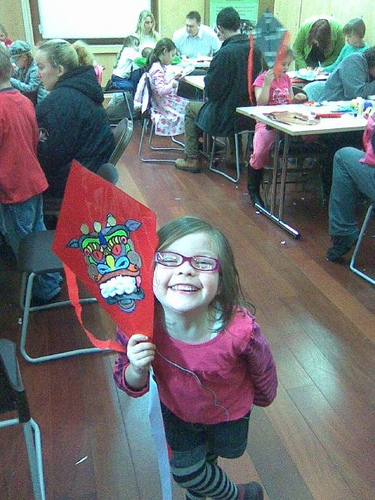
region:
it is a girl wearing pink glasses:
[156, 250, 220, 271]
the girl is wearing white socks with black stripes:
[180, 461, 217, 497]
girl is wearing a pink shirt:
[162, 338, 248, 423]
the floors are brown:
[285, 296, 351, 411]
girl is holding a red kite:
[64, 190, 166, 332]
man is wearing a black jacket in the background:
[204, 46, 258, 99]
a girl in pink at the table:
[259, 47, 294, 100]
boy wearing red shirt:
[1, 95, 48, 189]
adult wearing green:
[300, 15, 341, 65]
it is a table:
[245, 97, 371, 135]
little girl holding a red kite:
[51, 157, 160, 398]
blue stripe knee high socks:
[169, 462, 238, 498]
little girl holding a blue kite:
[246, 3, 287, 86]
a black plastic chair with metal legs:
[16, 159, 121, 363]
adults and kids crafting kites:
[112, 8, 373, 264]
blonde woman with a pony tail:
[35, 37, 93, 95]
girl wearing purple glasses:
[151, 250, 219, 272]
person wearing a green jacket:
[293, 20, 347, 71]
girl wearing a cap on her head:
[7, 39, 31, 60]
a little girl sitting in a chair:
[134, 37, 191, 161]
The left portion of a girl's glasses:
[191, 256, 224, 272]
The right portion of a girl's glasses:
[155, 248, 181, 270]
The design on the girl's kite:
[68, 223, 155, 314]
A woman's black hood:
[61, 70, 111, 98]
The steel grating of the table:
[248, 201, 300, 242]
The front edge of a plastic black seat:
[16, 230, 60, 276]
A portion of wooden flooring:
[271, 242, 322, 355]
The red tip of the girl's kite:
[62, 149, 92, 173]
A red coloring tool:
[316, 112, 347, 118]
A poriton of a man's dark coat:
[202, 52, 233, 102]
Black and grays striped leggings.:
[168, 450, 244, 498]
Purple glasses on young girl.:
[146, 210, 230, 319]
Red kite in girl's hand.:
[51, 159, 162, 354]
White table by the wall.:
[238, 104, 364, 132]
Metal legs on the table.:
[257, 125, 310, 236]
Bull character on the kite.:
[69, 216, 144, 314]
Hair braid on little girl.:
[108, 32, 141, 75]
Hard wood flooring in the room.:
[276, 270, 373, 496]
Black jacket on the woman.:
[29, 40, 117, 181]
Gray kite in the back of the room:
[253, 8, 281, 69]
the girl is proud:
[38, 139, 298, 426]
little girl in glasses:
[127, 216, 278, 375]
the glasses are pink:
[126, 209, 244, 353]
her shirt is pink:
[164, 282, 322, 429]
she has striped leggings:
[122, 411, 252, 486]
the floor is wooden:
[207, 295, 348, 488]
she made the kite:
[22, 127, 253, 417]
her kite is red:
[33, 140, 285, 435]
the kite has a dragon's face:
[33, 204, 198, 342]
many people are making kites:
[21, 18, 349, 436]